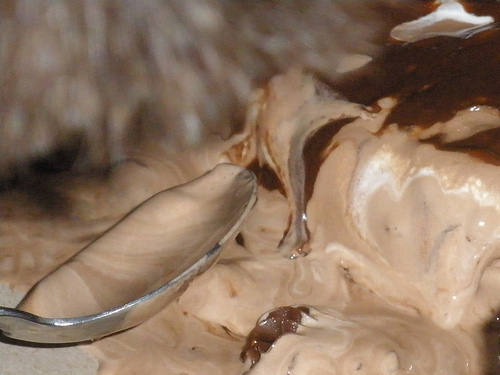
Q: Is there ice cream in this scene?
A: Yes, there is ice cream.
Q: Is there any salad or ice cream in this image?
A: Yes, there is ice cream.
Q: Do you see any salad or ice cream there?
A: Yes, there is ice cream.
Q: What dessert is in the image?
A: The dessert is ice cream.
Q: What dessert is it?
A: The dessert is ice cream.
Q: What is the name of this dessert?
A: That is ice cream.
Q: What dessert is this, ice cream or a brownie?
A: That is ice cream.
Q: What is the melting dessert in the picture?
A: The dessert is ice cream.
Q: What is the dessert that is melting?
A: The dessert is ice cream.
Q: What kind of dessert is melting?
A: The dessert is ice cream.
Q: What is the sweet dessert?
A: The dessert is ice cream.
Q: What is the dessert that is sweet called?
A: The dessert is ice cream.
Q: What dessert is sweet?
A: The dessert is ice cream.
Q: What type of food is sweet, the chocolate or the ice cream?
A: The ice cream is sweet.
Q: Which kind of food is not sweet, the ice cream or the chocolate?
A: The chocolate is not sweet.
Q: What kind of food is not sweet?
A: The food is chocolate.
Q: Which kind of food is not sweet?
A: The food is chocolate.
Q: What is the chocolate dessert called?
A: The dessert is ice cream.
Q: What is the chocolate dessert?
A: The dessert is ice cream.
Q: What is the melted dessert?
A: The dessert is ice cream.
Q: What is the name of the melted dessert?
A: The dessert is ice cream.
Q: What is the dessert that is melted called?
A: The dessert is ice cream.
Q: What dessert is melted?
A: The dessert is ice cream.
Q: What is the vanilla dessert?
A: The dessert is ice cream.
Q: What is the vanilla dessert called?
A: The dessert is ice cream.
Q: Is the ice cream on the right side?
A: Yes, the ice cream is on the right of the image.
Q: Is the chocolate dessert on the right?
A: Yes, the ice cream is on the right of the image.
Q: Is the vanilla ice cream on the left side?
A: No, the ice cream is on the right of the image.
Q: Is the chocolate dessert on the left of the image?
A: No, the ice cream is on the right of the image.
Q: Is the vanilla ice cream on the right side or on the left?
A: The ice cream is on the right of the image.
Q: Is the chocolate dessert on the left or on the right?
A: The ice cream is on the right of the image.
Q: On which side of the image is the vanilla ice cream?
A: The ice cream is on the right of the image.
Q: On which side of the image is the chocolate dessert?
A: The ice cream is on the right of the image.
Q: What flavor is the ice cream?
A: That is a vanilla ice cream.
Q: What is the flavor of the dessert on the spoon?
A: That is a vanilla ice cream.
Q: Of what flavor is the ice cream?
A: That is a vanilla ice cream.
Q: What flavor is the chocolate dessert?
A: That is a vanilla ice cream.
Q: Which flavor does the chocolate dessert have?
A: That is a vanilla ice cream.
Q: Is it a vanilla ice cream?
A: Yes, that is a vanilla ice cream.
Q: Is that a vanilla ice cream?
A: Yes, that is a vanilla ice cream.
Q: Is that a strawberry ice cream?
A: No, that is a vanilla ice cream.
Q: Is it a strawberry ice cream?
A: No, that is a vanilla ice cream.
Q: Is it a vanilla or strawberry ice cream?
A: That is a vanilla ice cream.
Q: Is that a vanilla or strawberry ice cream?
A: That is a vanilla ice cream.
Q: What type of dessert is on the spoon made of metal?
A: The dessert is ice cream.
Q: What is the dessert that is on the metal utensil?
A: The dessert is ice cream.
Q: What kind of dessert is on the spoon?
A: The dessert is ice cream.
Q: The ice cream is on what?
A: The ice cream is on the spoon.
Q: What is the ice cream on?
A: The ice cream is on the spoon.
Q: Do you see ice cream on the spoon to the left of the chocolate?
A: Yes, there is ice cream on the spoon.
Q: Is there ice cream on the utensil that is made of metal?
A: Yes, there is ice cream on the spoon.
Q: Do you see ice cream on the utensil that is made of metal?
A: Yes, there is ice cream on the spoon.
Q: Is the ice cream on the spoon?
A: Yes, the ice cream is on the spoon.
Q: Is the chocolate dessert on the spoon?
A: Yes, the ice cream is on the spoon.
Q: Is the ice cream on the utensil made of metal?
A: Yes, the ice cream is on the spoon.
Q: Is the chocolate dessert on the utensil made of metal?
A: Yes, the ice cream is on the spoon.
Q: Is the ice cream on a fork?
A: No, the ice cream is on the spoon.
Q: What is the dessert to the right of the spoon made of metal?
A: The dessert is ice cream.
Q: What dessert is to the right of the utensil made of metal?
A: The dessert is ice cream.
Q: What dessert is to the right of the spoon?
A: The dessert is ice cream.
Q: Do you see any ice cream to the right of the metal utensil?
A: Yes, there is ice cream to the right of the spoon.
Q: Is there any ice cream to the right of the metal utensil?
A: Yes, there is ice cream to the right of the spoon.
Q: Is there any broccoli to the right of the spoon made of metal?
A: No, there is ice cream to the right of the spoon.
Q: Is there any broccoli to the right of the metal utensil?
A: No, there is ice cream to the right of the spoon.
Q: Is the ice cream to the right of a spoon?
A: Yes, the ice cream is to the right of a spoon.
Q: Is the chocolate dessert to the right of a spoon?
A: Yes, the ice cream is to the right of a spoon.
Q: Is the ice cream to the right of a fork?
A: No, the ice cream is to the right of a spoon.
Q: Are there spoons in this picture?
A: Yes, there is a spoon.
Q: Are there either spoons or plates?
A: Yes, there is a spoon.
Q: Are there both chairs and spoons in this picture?
A: No, there is a spoon but no chairs.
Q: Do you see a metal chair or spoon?
A: Yes, there is a metal spoon.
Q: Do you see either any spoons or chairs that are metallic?
A: Yes, the spoon is metallic.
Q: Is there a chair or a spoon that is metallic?
A: Yes, the spoon is metallic.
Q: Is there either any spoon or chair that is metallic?
A: Yes, the spoon is metallic.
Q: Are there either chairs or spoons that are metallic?
A: Yes, the spoon is metallic.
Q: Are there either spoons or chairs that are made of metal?
A: Yes, the spoon is made of metal.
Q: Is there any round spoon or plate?
A: Yes, there is a round spoon.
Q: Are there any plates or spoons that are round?
A: Yes, the spoon is round.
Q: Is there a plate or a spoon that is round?
A: Yes, the spoon is round.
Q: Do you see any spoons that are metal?
A: Yes, there is a metal spoon.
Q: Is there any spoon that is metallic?
A: Yes, there is a spoon that is metallic.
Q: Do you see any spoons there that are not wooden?
A: Yes, there is a metallic spoon.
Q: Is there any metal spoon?
A: Yes, there is a spoon that is made of metal.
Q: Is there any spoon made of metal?
A: Yes, there is a spoon that is made of metal.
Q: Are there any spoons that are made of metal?
A: Yes, there is a spoon that is made of metal.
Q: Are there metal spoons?
A: Yes, there is a spoon that is made of metal.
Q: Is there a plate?
A: No, there are no plates.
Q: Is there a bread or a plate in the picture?
A: No, there are no plates or breads.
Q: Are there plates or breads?
A: No, there are no plates or breads.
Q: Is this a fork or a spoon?
A: This is a spoon.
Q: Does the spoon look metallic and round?
A: Yes, the spoon is metallic and round.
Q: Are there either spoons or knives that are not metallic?
A: No, there is a spoon but it is metallic.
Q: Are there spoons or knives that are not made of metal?
A: No, there is a spoon but it is made of metal.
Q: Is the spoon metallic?
A: Yes, the spoon is metallic.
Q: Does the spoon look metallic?
A: Yes, the spoon is metallic.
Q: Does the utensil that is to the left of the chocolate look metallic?
A: Yes, the spoon is metallic.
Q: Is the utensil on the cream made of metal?
A: Yes, the spoon is made of metal.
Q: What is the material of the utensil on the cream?
A: The spoon is made of metal.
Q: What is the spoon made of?
A: The spoon is made of metal.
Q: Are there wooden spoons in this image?
A: No, there is a spoon but it is metallic.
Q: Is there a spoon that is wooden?
A: No, there is a spoon but it is metallic.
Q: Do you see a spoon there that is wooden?
A: No, there is a spoon but it is metallic.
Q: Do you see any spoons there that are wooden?
A: No, there is a spoon but it is metallic.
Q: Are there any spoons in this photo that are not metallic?
A: No, there is a spoon but it is metallic.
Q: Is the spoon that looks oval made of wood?
A: No, the spoon is made of metal.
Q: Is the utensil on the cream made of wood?
A: No, the spoon is made of metal.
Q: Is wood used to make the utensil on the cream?
A: No, the spoon is made of metal.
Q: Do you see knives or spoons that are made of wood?
A: No, there is a spoon but it is made of metal.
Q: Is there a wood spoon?
A: No, there is a spoon but it is made of metal.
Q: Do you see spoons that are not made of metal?
A: No, there is a spoon but it is made of metal.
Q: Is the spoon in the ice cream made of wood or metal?
A: The spoon is made of metal.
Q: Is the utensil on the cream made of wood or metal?
A: The spoon is made of metal.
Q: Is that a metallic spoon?
A: Yes, that is a metallic spoon.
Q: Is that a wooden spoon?
A: No, that is a metallic spoon.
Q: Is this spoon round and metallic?
A: Yes, the spoon is round and metallic.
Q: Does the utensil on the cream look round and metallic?
A: Yes, the spoon is round and metallic.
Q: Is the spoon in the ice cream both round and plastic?
A: No, the spoon is round but metallic.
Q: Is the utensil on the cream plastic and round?
A: No, the spoon is round but metallic.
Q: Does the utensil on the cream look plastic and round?
A: No, the spoon is round but metallic.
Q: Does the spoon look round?
A: Yes, the spoon is round.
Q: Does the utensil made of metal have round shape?
A: Yes, the spoon is round.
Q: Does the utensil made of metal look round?
A: Yes, the spoon is round.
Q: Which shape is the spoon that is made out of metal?
A: The spoon is round.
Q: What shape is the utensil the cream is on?
A: The spoon is round.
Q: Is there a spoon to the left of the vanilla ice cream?
A: Yes, there is a spoon to the left of the ice cream.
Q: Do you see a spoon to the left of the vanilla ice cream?
A: Yes, there is a spoon to the left of the ice cream.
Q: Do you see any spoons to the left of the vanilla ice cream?
A: Yes, there is a spoon to the left of the ice cream.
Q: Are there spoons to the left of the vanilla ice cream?
A: Yes, there is a spoon to the left of the ice cream.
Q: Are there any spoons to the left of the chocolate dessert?
A: Yes, there is a spoon to the left of the ice cream.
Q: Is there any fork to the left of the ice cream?
A: No, there is a spoon to the left of the ice cream.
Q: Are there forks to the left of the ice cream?
A: No, there is a spoon to the left of the ice cream.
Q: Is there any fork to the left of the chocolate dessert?
A: No, there is a spoon to the left of the ice cream.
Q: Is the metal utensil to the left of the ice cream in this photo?
A: Yes, the spoon is to the left of the ice cream.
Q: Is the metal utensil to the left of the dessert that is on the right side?
A: Yes, the spoon is to the left of the ice cream.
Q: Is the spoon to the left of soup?
A: No, the spoon is to the left of the ice cream.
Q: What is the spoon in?
A: The spoon is in the ice cream.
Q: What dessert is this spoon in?
A: The spoon is in the ice cream.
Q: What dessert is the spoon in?
A: The spoon is in the ice cream.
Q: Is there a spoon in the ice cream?
A: Yes, there is a spoon in the ice cream.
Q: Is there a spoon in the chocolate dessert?
A: Yes, there is a spoon in the ice cream.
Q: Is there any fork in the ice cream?
A: No, there is a spoon in the ice cream.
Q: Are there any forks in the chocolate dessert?
A: No, there is a spoon in the ice cream.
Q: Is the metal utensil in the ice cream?
A: Yes, the spoon is in the ice cream.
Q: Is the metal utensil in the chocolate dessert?
A: Yes, the spoon is in the ice cream.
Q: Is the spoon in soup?
A: No, the spoon is in the ice cream.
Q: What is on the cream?
A: The spoon is on the cream.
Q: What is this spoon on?
A: The spoon is on the cream.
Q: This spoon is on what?
A: The spoon is on the cream.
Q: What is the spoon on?
A: The spoon is on the cream.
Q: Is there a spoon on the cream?
A: Yes, there is a spoon on the cream.